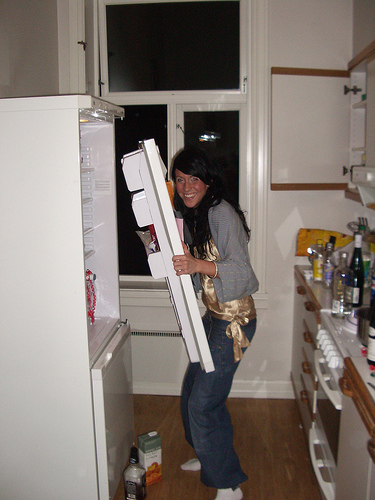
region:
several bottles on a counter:
[299, 230, 365, 308]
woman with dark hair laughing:
[166, 145, 252, 498]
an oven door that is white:
[307, 312, 346, 498]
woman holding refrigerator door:
[119, 136, 264, 499]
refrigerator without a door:
[4, 91, 130, 499]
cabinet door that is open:
[263, 51, 370, 204]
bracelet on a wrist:
[177, 242, 223, 284]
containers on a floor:
[117, 429, 166, 498]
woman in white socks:
[172, 145, 262, 499]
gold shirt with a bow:
[191, 207, 264, 365]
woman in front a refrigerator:
[7, 77, 271, 498]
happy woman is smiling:
[159, 138, 234, 251]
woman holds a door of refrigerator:
[32, 95, 270, 400]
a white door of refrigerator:
[116, 130, 214, 386]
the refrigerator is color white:
[1, 77, 136, 489]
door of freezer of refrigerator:
[57, 87, 214, 375]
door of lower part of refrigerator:
[72, 322, 138, 495]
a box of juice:
[135, 422, 171, 488]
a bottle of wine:
[343, 227, 367, 312]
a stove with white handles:
[302, 302, 364, 497]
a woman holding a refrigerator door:
[117, 130, 252, 416]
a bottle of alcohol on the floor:
[120, 443, 145, 499]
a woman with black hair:
[171, 145, 239, 259]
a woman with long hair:
[174, 140, 229, 262]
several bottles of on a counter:
[300, 238, 366, 314]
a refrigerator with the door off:
[70, 92, 132, 335]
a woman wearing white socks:
[167, 455, 257, 499]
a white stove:
[291, 332, 360, 495]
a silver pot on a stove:
[349, 299, 373, 348]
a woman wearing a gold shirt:
[204, 230, 239, 345]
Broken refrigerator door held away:
[118, 131, 258, 372]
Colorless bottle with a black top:
[123, 444, 150, 499]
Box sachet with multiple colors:
[134, 427, 166, 489]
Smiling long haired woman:
[163, 143, 272, 498]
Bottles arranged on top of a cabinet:
[302, 231, 374, 375]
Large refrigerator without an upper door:
[1, 85, 144, 498]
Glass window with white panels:
[92, 0, 260, 288]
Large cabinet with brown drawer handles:
[286, 261, 373, 443]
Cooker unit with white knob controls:
[307, 307, 374, 498]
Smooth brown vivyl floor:
[111, 388, 323, 498]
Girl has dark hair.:
[172, 159, 242, 246]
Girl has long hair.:
[168, 146, 258, 255]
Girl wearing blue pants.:
[175, 355, 257, 442]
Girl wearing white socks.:
[187, 457, 235, 492]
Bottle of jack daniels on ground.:
[125, 437, 144, 498]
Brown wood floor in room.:
[246, 400, 296, 482]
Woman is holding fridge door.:
[161, 233, 209, 310]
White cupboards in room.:
[337, 411, 358, 486]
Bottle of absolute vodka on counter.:
[330, 249, 355, 318]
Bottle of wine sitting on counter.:
[351, 233, 363, 305]